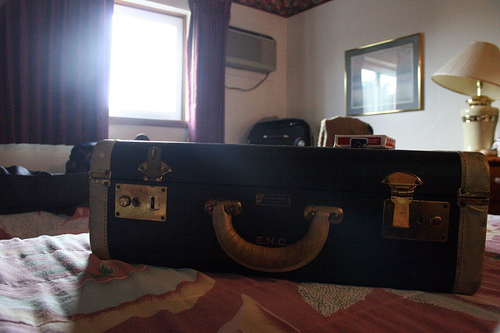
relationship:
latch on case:
[378, 174, 423, 238] [58, 134, 492, 289]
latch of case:
[383, 172, 423, 229] [58, 134, 492, 289]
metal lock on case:
[375, 169, 426, 234] [58, 134, 492, 289]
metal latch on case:
[384, 170, 409, 232] [119, 141, 405, 278]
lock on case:
[108, 183, 179, 214] [68, 127, 495, 306]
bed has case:
[28, 242, 143, 322] [58, 134, 492, 289]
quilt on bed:
[109, 278, 269, 318] [0, 212, 498, 331]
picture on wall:
[345, 34, 424, 116] [293, 30, 318, 85]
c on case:
[273, 224, 298, 254] [62, 135, 497, 265]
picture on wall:
[345, 34, 424, 116] [284, 25, 336, 107]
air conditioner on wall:
[221, 22, 279, 92] [229, 14, 484, 221]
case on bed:
[87, 137, 490, 294] [110, 101, 475, 321]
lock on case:
[108, 183, 179, 223] [87, 137, 490, 294]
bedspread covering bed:
[0, 217, 499, 329] [0, 212, 498, 331]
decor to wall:
[344, 22, 429, 126] [253, 20, 460, 224]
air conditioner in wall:
[221, 22, 279, 92] [260, 12, 480, 209]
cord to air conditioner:
[229, 69, 270, 95] [227, 26, 278, 76]